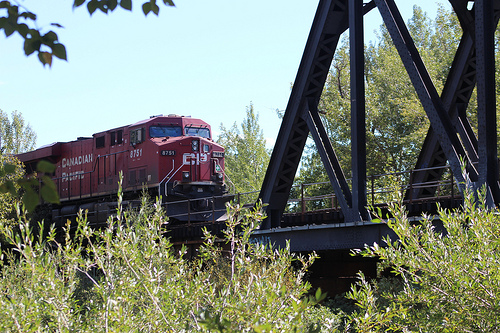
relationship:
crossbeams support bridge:
[231, 7, 498, 219] [1, 159, 498, 255]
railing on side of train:
[1, 183, 498, 240] [18, 114, 192, 214]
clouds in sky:
[78, 59, 257, 91] [13, 6, 403, 165]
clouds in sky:
[78, 59, 150, 90] [0, 1, 320, 143]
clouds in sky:
[78, 59, 257, 91] [1, 0, 498, 113]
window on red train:
[150, 122, 184, 139] [1, 114, 238, 229]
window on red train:
[130, 130, 140, 141] [1, 112, 233, 219]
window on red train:
[150, 122, 184, 139] [1, 112, 233, 219]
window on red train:
[183, 125, 209, 139] [1, 112, 233, 219]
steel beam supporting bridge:
[301, 110, 356, 222] [233, 0, 498, 257]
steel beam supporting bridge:
[364, 0, 495, 215] [233, 0, 498, 257]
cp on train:
[179, 146, 211, 168] [1, 114, 234, 242]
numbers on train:
[127, 144, 144, 160] [1, 114, 234, 242]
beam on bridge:
[256, 0, 347, 228] [233, 0, 498, 257]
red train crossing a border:
[1, 114, 238, 229] [8, 0, 497, 254]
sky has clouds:
[1, 0, 475, 172] [183, 81, 324, 176]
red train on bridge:
[1, 114, 238, 229] [41, 0, 498, 255]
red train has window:
[1, 114, 238, 229] [142, 109, 184, 146]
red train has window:
[1, 114, 238, 229] [186, 110, 216, 148]